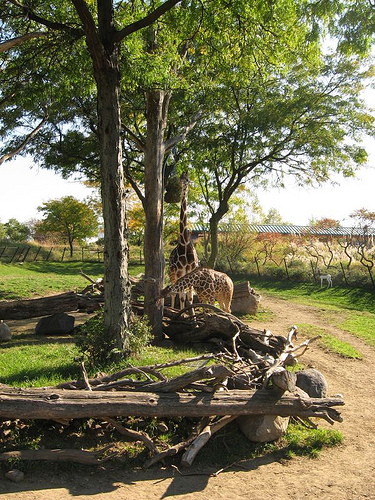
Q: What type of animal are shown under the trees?
A: Giraffes.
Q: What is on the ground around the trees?
A: Grass.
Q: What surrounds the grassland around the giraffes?
A: Fence.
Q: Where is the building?
A: Background.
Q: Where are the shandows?
A: Ground.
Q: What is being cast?
A: Shadows.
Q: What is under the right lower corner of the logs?
A: Rocks.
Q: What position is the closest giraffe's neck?
A: Bent downward.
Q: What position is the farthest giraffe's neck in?
A: Straight up.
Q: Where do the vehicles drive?
A: Between the logs and the fence.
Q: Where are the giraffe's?
A: Under the tree.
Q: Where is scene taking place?
A: Wildlife preserve.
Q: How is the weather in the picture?
A: Sunny and warm.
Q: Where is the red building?
A: Behind the giraffes on the right.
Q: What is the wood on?
A: Green grass.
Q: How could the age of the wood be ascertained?
A: Examination.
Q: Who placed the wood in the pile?
A: Zoo workers.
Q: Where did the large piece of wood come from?
A: Large dead tree.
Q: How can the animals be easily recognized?
A: Unusual skin pattern.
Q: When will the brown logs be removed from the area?
A: Capable workers available.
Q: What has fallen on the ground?
A: A log.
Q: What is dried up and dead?
A: Tree.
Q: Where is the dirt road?
A: By the trees.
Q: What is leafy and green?
A: Tree.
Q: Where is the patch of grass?
A: Along the road.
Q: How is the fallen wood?
A: Dead.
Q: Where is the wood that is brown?
A: In the grass.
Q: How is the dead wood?
A: Fallen.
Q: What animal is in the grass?
A: Giraffe.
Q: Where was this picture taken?
A: Animal preserve.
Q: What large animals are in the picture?
A: Giraffes.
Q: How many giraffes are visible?
A: Two.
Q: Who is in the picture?
A: No one.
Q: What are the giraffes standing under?
A: Trees.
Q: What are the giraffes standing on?
A: Path.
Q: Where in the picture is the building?
A: Right.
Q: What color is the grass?
A: Green.